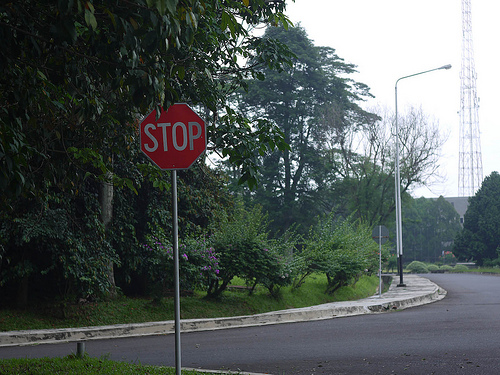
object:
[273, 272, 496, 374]
road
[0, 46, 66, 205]
trees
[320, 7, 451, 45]
sky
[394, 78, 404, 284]
lamp posts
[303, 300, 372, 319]
sidewalk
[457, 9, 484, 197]
tower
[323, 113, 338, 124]
scene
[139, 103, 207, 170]
sign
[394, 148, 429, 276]
light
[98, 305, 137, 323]
grass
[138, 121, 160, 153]
s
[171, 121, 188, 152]
o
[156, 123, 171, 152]
t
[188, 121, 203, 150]
p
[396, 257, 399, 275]
paint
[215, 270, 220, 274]
flowers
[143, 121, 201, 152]
stop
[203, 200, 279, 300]
bushes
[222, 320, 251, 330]
curb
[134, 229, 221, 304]
shrubs